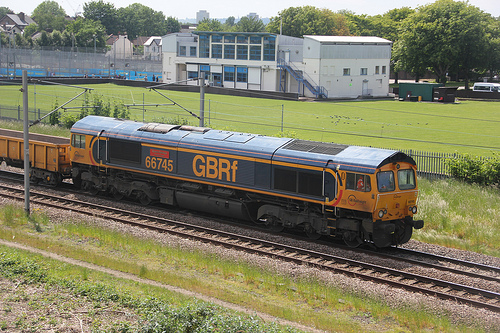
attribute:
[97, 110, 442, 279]
train — black, yellow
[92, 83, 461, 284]
train — metal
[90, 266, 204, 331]
grass — short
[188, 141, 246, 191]
letters — orange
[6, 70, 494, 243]
lawn — green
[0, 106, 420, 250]
train — yellow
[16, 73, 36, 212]
pole — gray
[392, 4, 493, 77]
leaves — green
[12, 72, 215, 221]
poles — metal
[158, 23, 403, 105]
building — white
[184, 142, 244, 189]
lettering — yellow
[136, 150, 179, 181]
numbers — yellow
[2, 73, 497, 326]
grass — tall, green, trimmed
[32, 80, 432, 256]
train — gray , Yellow 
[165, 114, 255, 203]
letters — Yellow , capital 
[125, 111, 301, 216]
numbers — Yellow 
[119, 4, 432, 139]
building — blue , White 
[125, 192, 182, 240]
plank — wooden 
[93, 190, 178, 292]
plank — wooden 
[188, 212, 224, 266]
plank — wooden 